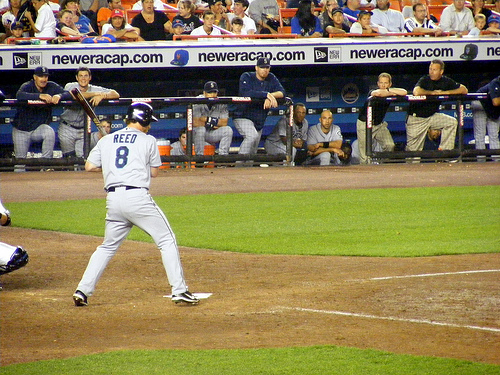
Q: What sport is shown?
A: Baseball.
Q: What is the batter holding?
A: Baseball bat.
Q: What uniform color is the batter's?
A: Blue.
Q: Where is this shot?
A: Ball park.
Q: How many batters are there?
A: 1.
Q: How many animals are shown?
A: 0.